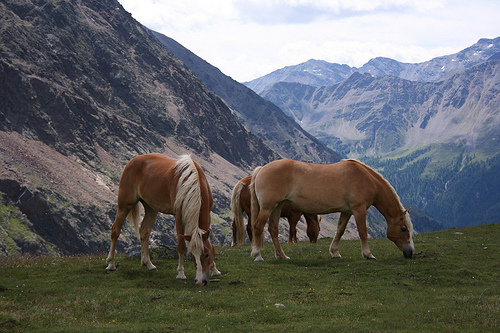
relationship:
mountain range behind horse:
[1, 2, 498, 257] [230, 175, 322, 241]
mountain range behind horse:
[1, 2, 498, 257] [249, 153, 419, 262]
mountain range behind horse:
[1, 2, 498, 257] [102, 144, 224, 286]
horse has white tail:
[243, 145, 418, 271] [230, 182, 246, 249]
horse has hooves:
[102, 144, 224, 286] [104, 261, 219, 279]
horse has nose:
[102, 144, 224, 286] [191, 270, 212, 287]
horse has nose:
[226, 168, 324, 247] [394, 239, 418, 261]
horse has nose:
[249, 153, 419, 262] [305, 230, 322, 247]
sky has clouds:
[116, 0, 498, 86] [126, 2, 446, 29]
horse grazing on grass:
[249, 153, 419, 262] [2, 261, 499, 330]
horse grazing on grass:
[102, 144, 224, 286] [2, 261, 499, 330]